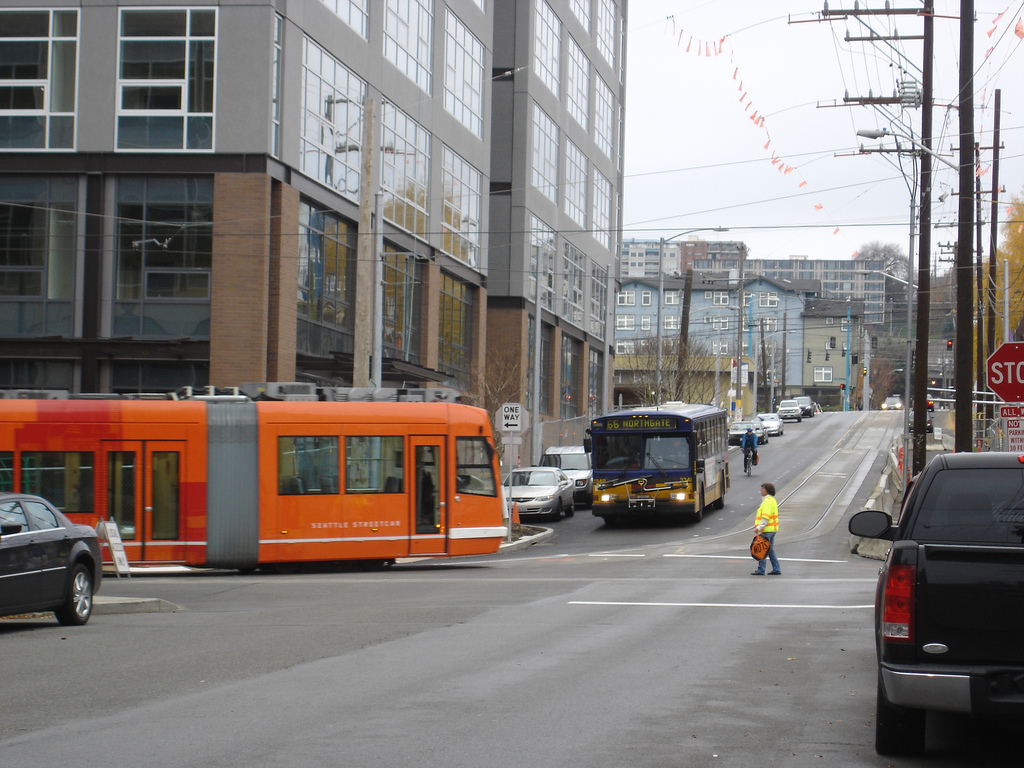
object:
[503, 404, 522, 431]
sign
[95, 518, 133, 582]
sign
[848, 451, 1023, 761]
truck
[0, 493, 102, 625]
car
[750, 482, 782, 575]
crossing guard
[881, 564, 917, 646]
headlight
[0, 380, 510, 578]
bus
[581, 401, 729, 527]
bus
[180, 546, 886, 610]
crosswalk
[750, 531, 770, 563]
sign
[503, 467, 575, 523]
car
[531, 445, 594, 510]
car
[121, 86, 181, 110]
window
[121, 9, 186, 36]
window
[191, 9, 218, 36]
window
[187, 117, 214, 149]
window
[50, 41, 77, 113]
window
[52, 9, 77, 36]
window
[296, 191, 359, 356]
window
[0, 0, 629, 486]
building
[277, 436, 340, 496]
window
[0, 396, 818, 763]
truck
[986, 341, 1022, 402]
stop sign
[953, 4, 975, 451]
light pole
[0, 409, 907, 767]
road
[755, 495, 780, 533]
safety jacket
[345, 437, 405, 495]
window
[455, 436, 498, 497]
window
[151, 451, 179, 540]
window